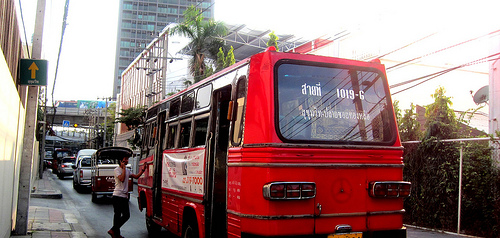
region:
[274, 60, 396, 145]
back windshield on bus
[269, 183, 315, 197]
brake light on bus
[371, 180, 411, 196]
brake light on bus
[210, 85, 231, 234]
door on the bus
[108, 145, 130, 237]
person standing next to the bus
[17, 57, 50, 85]
sign on the wall of building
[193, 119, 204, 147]
window on the bus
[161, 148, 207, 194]
sign on the bus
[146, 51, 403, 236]
red bus near the curb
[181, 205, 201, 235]
tire on the bus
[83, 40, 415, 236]
the bus is red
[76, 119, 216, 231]
a man beside a bus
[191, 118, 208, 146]
tinted window on bus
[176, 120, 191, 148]
tinted window on bus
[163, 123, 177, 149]
tinted window on bus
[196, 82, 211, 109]
tinted window on bus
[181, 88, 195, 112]
tinted window on bus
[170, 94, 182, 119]
tinted window on bus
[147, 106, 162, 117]
tinted window on bus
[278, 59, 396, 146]
tinted window on bus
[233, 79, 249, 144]
tinted window on bus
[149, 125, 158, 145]
tinted window on bus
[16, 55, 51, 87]
black street sign mounted on a pole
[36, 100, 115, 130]
bridge across a city street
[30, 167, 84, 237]
tiled sidewalk along a street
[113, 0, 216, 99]
tall apartment building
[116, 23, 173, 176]
orange and white facade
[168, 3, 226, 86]
palm tree in an urban area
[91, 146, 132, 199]
red and white vehicle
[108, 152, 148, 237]
man talking on a cell phone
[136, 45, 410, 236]
red city bus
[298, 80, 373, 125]
Thai writing on the rear window of a bus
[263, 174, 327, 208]
Light on a bus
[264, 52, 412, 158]
Front window on a bus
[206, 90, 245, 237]
Door on a bus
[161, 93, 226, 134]
Windows on a bus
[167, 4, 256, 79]
Palm tree by a bus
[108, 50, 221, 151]
Building by a bus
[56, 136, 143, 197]
Cars on a road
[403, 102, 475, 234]
Green tree by a road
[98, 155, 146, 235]
Man by a bus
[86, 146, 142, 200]
Car on the road by a bus